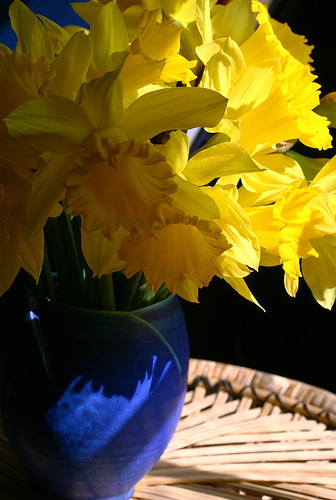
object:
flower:
[3, 50, 229, 241]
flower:
[194, 1, 332, 159]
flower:
[240, 154, 336, 297]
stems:
[80, 219, 130, 279]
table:
[128, 357, 335, 499]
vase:
[0, 293, 190, 500]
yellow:
[63, 137, 177, 243]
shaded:
[0, 167, 68, 297]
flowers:
[117, 211, 232, 296]